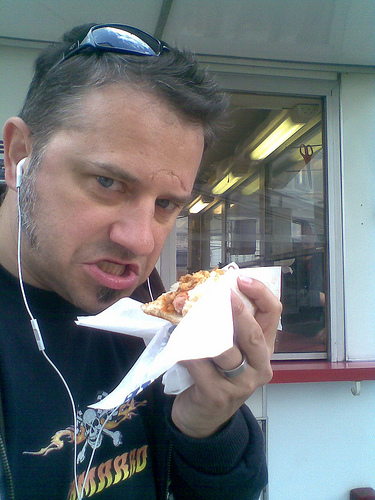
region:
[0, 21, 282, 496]
man eating hot dog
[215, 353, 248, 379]
silver band on mans finger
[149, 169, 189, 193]
scar on mans forehead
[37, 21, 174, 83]
blue sunglasses on mans head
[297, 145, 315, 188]
red scissors hanging in window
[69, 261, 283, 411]
hot dog wrapped in napkin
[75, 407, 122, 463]
white skull on shirt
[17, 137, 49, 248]
grey and black sideburn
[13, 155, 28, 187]
white earbud in mans ear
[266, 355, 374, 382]
red counter behind man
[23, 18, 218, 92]
sunglasses on top of man's head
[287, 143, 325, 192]
hanging pair of scissors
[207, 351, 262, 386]
silver ring on man's ring finger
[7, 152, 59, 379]
white earphones with volume control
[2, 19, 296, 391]
man trying to eat pizza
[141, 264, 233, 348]
pizza with lots of meat on it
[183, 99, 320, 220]
fluorescent lights seen from window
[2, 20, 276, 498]
man wearing a black shirt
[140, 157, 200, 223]
scar on top of man's eyebrow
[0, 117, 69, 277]
man's long side burn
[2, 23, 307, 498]
The man is making a face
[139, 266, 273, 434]
the man is holding some food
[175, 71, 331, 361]
there is a window behind the man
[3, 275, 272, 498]
the man is wearing a black shirt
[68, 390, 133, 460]
there is a skull and crossbones on his shirt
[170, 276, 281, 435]
the man has a ring on his finger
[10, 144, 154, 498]
the man is wearing white earbuds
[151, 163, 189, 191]
there is a scar on the man's forhead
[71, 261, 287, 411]
white paper surrounds the food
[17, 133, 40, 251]
the man has graying sideburns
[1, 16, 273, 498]
middle aged man was once punkrocker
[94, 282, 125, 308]
middle aged man has greying soul patch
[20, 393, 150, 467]
middle aged man shirt has blazing skull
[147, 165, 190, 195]
middle aged man has big weird scar above eyebrow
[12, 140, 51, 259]
middle aged man has greying rockabilly sideburn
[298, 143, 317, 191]
giant red scissors with red handle hangs inside shop window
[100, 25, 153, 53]
bright light reflected in middle aged man's sunglasses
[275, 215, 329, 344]
man inside shop looks downwards, has at least one crossed arm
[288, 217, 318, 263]
man inside shop wears goofy expression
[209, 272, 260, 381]
middle aged man wears silver wedding ring, unpolished fingernail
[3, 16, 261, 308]
a man with short hair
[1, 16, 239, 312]
a man with glasses on his head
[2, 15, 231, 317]
a man with buds in his ears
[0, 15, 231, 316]
a man with a scar on his forehead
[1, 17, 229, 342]
a man with a scruffy beard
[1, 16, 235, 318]
a man glaring at the camera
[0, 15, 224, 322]
a man with an unattractive snarl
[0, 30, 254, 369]
a man displeased with his hot dog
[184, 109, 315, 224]
three fluorescent lights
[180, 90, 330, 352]
scissors mysteriously suspended in air